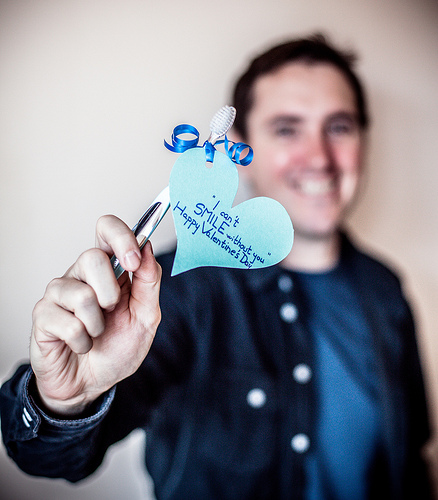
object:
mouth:
[295, 172, 342, 199]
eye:
[274, 124, 299, 140]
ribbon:
[163, 123, 253, 166]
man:
[0, 26, 437, 500]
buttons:
[22, 407, 33, 428]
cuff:
[9, 365, 118, 446]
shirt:
[3, 224, 436, 497]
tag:
[168, 146, 295, 276]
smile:
[290, 171, 341, 203]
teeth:
[296, 176, 336, 192]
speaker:
[163, 123, 254, 167]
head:
[209, 104, 237, 136]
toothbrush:
[112, 105, 239, 279]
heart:
[170, 146, 295, 277]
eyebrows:
[266, 108, 356, 124]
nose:
[302, 124, 334, 173]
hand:
[30, 215, 163, 402]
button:
[278, 277, 294, 293]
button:
[280, 301, 298, 322]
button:
[292, 363, 313, 384]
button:
[290, 433, 310, 454]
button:
[246, 387, 268, 409]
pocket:
[202, 373, 285, 474]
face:
[246, 62, 365, 233]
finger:
[34, 299, 93, 354]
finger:
[46, 275, 106, 339]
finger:
[66, 249, 122, 312]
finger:
[95, 215, 142, 272]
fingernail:
[124, 249, 141, 271]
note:
[173, 199, 266, 270]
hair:
[227, 34, 369, 138]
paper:
[169, 145, 297, 283]